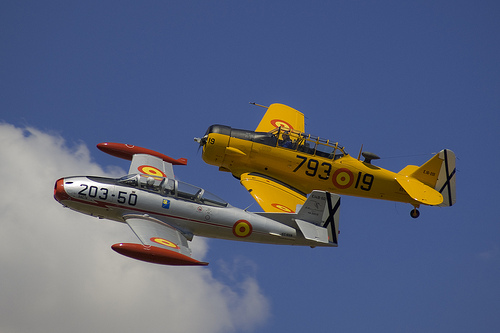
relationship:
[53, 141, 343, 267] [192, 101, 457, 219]
airplane flying together with airplane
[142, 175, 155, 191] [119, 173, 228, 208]
pilot sitting in cockpit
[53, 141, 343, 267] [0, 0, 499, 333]
airplane flying in sky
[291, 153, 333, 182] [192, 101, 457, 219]
793 on side of airplane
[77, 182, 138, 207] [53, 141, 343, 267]
203-50 on side of airplane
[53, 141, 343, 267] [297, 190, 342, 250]
airplane has tail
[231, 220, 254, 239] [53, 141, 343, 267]
circle on side of airplane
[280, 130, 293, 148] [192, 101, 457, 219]
pilot inside of airplane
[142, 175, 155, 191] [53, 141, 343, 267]
pilot inside of airplane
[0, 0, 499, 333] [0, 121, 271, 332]
sky has cloud